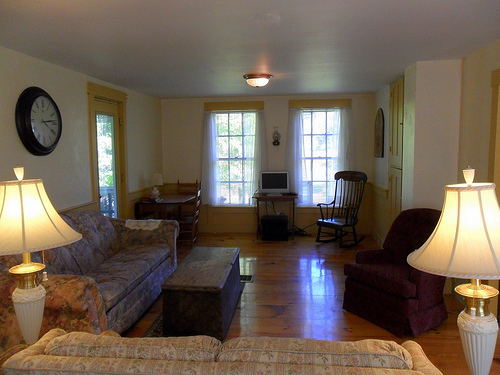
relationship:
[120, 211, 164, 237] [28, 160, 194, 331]
cloth on couch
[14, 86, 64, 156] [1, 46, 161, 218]
clock on wall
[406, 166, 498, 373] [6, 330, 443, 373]
lamp to right of couch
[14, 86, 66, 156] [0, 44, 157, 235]
clock on wall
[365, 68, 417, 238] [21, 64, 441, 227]
door flush with wall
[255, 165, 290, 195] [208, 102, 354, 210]
monitor between windows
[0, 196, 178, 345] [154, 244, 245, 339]
couch behind coffe table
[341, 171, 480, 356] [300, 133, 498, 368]
corner has chairs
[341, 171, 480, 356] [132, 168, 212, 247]
corner has table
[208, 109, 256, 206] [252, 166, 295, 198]
window to left of television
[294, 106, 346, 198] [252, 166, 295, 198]
window to right of television